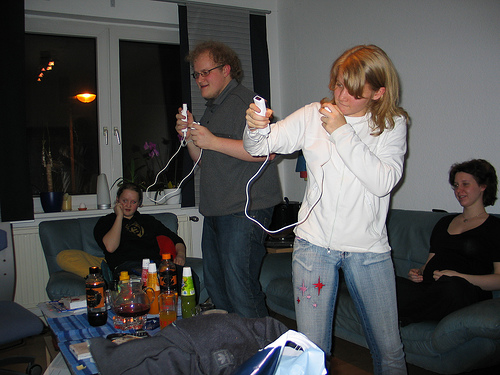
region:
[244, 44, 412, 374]
woman playing video game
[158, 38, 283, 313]
man playing video game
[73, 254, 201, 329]
a congregation of bottles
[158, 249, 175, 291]
a grey Gatorade bottle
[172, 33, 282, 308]
a guy wearing corrective glasses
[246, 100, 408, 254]
a white long sleeve shirt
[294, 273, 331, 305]
doodles on blue jeans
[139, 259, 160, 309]
plastic bottles with orange liquid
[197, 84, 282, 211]
a grey short sleeve collard shirt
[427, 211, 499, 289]
a black top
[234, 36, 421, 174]
a woman holding a game controller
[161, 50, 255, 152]
a man holding a game controller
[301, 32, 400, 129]
a woman with blonde hair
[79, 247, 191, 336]
several drink bottles on a table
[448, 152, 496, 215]
a woman with brown hair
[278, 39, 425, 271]
a woman wearing a white shirt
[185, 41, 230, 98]
a man wearing glasses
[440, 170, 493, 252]
a woman wearing a necklace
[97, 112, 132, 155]
silver handles on a window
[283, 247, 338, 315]
blue jeans with red and pink stars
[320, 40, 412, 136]
a blonde woman with shoulder length hair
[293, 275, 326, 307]
pink and red stars on blue jeans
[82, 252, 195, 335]
assortment of bottle on a table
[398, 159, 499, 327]
woman sitting cross legged on a couch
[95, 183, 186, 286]
woman sitting in an armchair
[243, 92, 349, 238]
woman holding a gaming controller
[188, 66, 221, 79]
man wearing glasses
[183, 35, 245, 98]
man with blond wavy hair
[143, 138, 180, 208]
a purple orchid in a white pot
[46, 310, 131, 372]
a blue stripe place mat on a table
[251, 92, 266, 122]
a white wii remote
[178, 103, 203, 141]
man holding a wii remote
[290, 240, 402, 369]
woman wearing blue jeans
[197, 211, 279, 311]
man wearing blue jeans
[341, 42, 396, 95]
woman has blonde hair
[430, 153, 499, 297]
woman with black shirt on sofa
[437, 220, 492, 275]
woman wearing black shirt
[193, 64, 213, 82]
man is wearing glasses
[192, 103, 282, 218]
man has a grey shirt on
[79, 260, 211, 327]
bottles on the table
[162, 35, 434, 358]
People playing wii game.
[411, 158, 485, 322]
A lady sitting on the sofa.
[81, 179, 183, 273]
A person sitting in the chair.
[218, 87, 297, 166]
A woman with wii controller in hand.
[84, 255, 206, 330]
Bottle of drinks on the table.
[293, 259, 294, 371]
Stars on the jeans.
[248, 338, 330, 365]
Plastic bag on table.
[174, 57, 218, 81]
The man is wearing glasses.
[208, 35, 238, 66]
The man has curly blonde hair.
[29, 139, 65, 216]
A plant in the window pane.